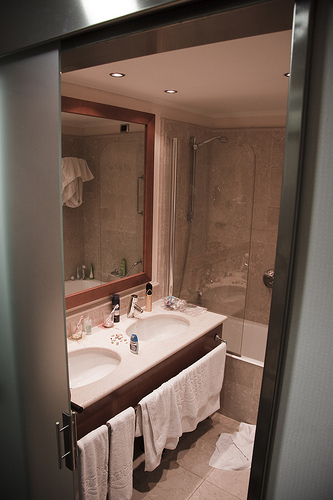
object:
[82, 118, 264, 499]
doorway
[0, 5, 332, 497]
bathroom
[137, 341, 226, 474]
towels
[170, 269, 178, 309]
toothbrushes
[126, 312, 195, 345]
sink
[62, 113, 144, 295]
mirror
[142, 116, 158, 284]
frame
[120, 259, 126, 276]
body wash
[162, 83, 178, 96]
lights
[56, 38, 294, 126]
ceiling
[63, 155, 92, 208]
towel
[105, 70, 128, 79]
light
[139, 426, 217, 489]
shadow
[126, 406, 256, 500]
floor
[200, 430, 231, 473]
napkin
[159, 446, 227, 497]
tiles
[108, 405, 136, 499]
towel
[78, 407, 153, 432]
rack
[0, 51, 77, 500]
door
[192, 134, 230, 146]
shower head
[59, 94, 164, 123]
edge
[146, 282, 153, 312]
can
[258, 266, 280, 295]
handle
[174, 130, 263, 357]
shower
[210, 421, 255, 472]
towel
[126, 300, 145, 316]
faucet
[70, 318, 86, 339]
toothbrush holder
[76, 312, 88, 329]
toothbrushes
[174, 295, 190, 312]
soap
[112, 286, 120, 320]
shaving cream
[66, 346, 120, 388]
sinks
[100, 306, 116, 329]
glass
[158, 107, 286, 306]
shield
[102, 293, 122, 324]
canister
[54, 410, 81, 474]
door handle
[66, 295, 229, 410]
counter